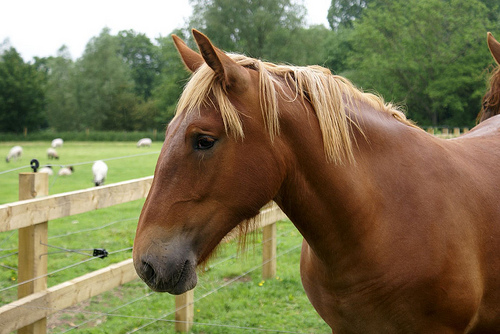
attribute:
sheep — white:
[89, 159, 110, 186]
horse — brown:
[142, 60, 476, 301]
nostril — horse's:
[137, 253, 156, 285]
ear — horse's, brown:
[189, 17, 261, 95]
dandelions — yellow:
[248, 265, 298, 316]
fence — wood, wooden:
[1, 169, 286, 331]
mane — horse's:
[169, 47, 417, 169]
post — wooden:
[16, 170, 48, 332]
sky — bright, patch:
[3, 1, 371, 79]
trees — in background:
[378, 3, 470, 86]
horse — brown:
[125, 22, 497, 329]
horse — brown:
[473, 28, 499, 122]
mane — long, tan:
[164, 44, 432, 181]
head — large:
[125, 19, 315, 300]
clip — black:
[88, 240, 110, 262]